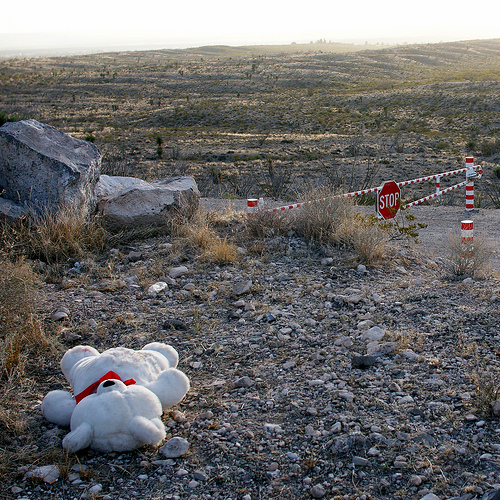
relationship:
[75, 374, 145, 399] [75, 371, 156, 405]
ribbon on neck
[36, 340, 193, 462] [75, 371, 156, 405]
teddy bear has neck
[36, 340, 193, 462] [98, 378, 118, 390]
teddy bear has nose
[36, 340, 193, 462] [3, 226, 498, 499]
teddy bear laying on ground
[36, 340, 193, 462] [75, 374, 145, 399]
teddy bear has ribbon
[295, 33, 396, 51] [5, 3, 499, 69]
buildings in distance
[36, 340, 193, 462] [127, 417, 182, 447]
teddy bear has ear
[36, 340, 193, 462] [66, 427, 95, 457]
teddy bear has ear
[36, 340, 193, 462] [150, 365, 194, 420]
teddy bear has arm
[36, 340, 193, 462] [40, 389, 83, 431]
teddy bear has arm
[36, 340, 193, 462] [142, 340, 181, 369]
teddy bear has foot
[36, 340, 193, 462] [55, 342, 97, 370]
teddy bear has foot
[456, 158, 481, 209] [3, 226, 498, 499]
pole in ground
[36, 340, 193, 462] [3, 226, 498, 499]
teddy bear on ground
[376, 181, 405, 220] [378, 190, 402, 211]
sign has letters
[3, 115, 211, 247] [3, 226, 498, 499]
boulder on ground